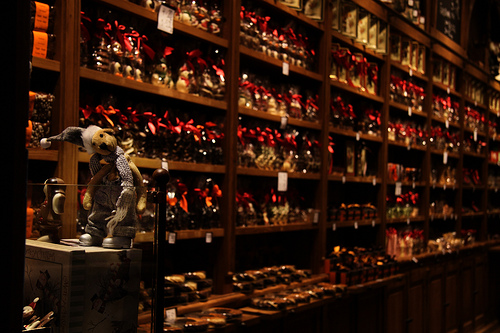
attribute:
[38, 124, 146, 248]
dog — brown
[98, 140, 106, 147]
nose — black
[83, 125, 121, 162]
dog face — brown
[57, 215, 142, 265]
shoes — White 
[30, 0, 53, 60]
labels — orange 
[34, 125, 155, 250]
animal — stuffed